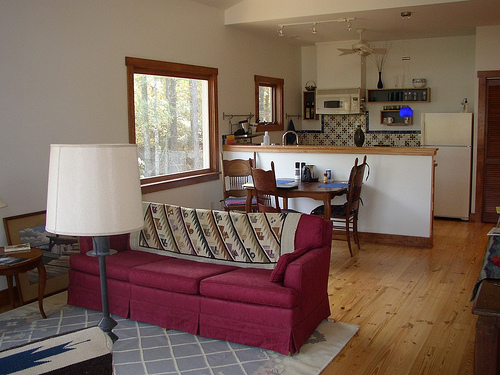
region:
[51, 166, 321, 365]
the couch is red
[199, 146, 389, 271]
brown wooden dining set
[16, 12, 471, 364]
living room and kitchen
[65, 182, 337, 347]
red sofa with blanket over it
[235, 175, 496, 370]
light colored hardwood floors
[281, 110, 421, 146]
tiled backsplash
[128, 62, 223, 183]
window in the dining area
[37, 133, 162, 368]
floor lamp with cream shade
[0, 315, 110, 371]
blanket with a mosaic pattern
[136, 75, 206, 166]
trees outside of the window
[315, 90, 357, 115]
microwave in the kitchen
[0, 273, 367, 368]
blue and cream area rug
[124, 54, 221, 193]
Brown framed window near the chair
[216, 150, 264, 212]
brown chair near the window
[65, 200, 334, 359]
Red sofa in the living room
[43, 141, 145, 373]
Lamp stand in the living room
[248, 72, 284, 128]
Small window in the kitchen area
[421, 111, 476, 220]
White refrigderator in the kitchen area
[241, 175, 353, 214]
Brown table near the window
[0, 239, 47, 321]
End table near the sofa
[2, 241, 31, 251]
A book on the table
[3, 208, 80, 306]
Picture frame on the ground near the sofa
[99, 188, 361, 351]
a couch in a house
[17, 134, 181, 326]
a lamp in a house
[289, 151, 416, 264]
a chair in a house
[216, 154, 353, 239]
a table in a house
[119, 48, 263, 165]
a window in a house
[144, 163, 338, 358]
a pink couch in a house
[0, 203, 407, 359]
a rug in a house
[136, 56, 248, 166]
curtains on a window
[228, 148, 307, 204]
a chair at a table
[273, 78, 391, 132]
a microwave in a kitchen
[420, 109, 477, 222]
A white refrigerator in the kitchen.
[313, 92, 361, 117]
A microwave in the kitchen.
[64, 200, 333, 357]
A couch with a blanket on it.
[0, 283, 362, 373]
A rug on the floor.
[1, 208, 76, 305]
A painting on the floor.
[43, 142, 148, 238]
A white lamp shade.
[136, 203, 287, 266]
A pattern on the blanket.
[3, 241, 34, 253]
A book on the table.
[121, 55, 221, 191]
A window showing outdoors.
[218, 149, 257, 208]
A empty brown chair.